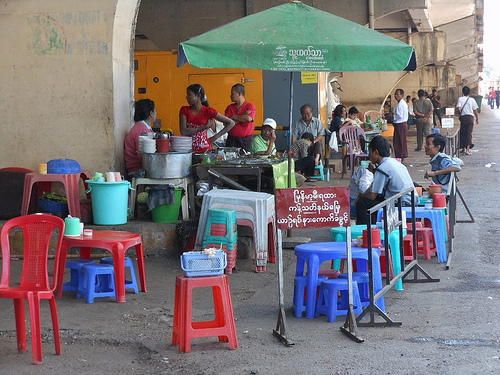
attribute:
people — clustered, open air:
[142, 83, 476, 221]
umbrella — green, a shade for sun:
[177, 4, 417, 180]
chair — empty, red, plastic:
[3, 212, 74, 362]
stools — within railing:
[202, 209, 244, 278]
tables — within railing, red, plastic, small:
[69, 230, 146, 300]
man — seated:
[249, 115, 278, 153]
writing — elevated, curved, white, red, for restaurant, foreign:
[278, 191, 349, 232]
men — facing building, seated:
[357, 133, 463, 220]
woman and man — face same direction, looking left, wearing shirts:
[180, 82, 257, 151]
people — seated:
[252, 106, 457, 216]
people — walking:
[388, 86, 483, 155]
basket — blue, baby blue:
[179, 250, 229, 276]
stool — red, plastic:
[173, 277, 238, 352]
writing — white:
[266, 45, 333, 73]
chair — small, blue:
[71, 258, 140, 304]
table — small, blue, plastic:
[291, 237, 385, 316]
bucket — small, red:
[365, 227, 383, 249]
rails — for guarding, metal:
[356, 166, 476, 323]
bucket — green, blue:
[85, 174, 130, 225]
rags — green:
[92, 167, 104, 180]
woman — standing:
[179, 86, 239, 153]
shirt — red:
[185, 107, 221, 151]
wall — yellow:
[143, 0, 326, 149]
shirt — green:
[251, 134, 280, 156]